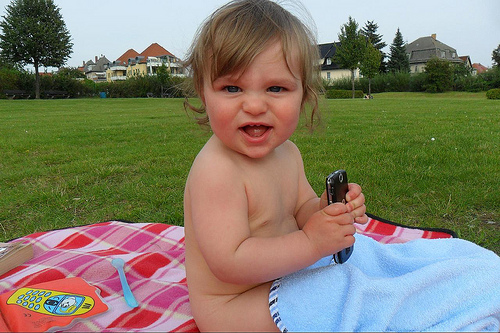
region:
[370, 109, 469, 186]
grass is green color.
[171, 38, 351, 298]
One baby is seen.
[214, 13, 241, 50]
Hair is blonde color.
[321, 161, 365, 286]
baby is holding cellphone.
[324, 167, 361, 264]
cellphone is black color.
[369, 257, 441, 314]
towel is blue color.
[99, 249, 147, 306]
Spoon is on the towel.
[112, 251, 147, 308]
Spoon is blue color.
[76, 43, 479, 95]
Houses are behind the baby.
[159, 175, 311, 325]
Baby is sitting in the grass.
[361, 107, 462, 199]
part of a green grass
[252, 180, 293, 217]
chest of a baby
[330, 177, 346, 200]
part of a phone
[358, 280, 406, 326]
part of a blue cloth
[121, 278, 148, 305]
handle of a spoon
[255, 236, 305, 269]
right arm of a baby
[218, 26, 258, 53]
hair of a baby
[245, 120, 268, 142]
mouth of a baby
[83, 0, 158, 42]
part of the sky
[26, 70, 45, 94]
stem of a tree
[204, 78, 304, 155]
Happy baby face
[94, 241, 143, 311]
Blue feeding spoon on blanket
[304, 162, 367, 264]
Cell phone in baby's hands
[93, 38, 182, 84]
Houses in the background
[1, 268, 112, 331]
baby toy on blanket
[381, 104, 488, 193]
grassy field in background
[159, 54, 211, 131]
Curly hair on baby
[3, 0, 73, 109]
Tall tree to the left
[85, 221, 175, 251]
Pink patterned blanket under baby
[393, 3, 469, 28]
clear blue skies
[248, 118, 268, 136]
Four baby teeth coming in.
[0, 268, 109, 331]
A toy book for the baby.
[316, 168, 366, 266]
A black smart phone with a camera.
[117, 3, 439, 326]
A smiling baby on a blanket.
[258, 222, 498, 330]
A fuzzy blue blanket covering the baby.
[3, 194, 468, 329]
A red flannel blanket on the ground.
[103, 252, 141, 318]
A blue plastic spoon on the blanket.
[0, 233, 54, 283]
A novel on the red blanket.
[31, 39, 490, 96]
A really nice neighborhood.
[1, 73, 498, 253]
Green grass in a yard.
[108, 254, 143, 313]
light blue plastic spoon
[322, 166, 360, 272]
black smart cell phone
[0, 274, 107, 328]
Children's soft book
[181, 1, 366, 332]
naked toddler sitting on a blanket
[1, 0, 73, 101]
green tree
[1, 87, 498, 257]
many blades of green grass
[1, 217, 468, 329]
pink and red blanket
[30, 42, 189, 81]
Large homes in background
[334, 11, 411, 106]
four green trees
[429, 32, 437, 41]
red chimney on grey roof